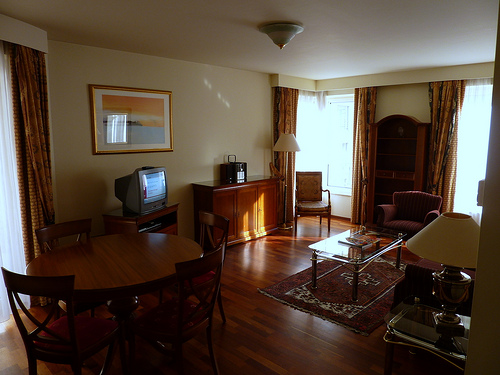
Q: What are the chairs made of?
A: Wood.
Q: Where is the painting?
A: On the wall.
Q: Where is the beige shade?
A: On the table lamp.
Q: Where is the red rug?
A: Under the table.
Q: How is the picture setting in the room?
A: On the wall.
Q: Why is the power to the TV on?
A: To watch.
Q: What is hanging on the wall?
A: Portrait.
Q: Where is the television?
A: TV stand.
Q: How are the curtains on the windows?
A: Pulled to the sides.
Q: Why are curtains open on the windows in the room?
A: To provide sunlight.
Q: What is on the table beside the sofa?
A: Lamp.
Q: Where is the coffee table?
A: Floor in middle of the living room.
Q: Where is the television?
A: In the open, on a small table.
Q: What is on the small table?
A: A television.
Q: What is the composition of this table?
A: It is made of wood.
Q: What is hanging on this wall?
A: A painting.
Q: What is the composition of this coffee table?
A: It is made of glass.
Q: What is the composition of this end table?
A: It is made of glass.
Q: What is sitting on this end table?
A: A lamp.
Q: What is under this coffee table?
A: A burgundy rug.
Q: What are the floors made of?
A: Wood.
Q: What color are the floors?
A: Brown.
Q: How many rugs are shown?
A: One.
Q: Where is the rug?
A: On the floor.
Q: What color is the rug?
A: Red.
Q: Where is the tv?
A: On stand.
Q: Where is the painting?
A: On the wall.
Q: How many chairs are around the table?
A: Four.